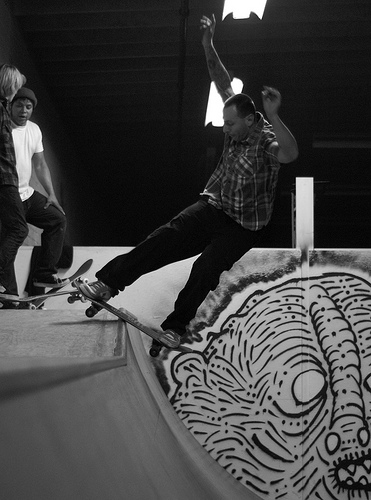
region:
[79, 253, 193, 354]
person on the skate board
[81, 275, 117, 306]
man wearing gray shoes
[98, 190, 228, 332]
man wearing black pants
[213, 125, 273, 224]
man wearing a plaid shirt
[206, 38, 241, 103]
man with tattoo on its arm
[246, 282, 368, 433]
graffiti on the wall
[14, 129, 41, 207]
man wearing a white shirt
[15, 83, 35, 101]
man wearing a hat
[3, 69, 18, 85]
man with blond hair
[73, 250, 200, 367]
man doing a trick on a skate board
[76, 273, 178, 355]
skateboard on the edge of the ramp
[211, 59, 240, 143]
light fixture in the ceiling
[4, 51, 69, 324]
people standing at the top of the ramp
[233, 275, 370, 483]
wall painted graffiti style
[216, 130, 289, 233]
person wearing a plaid shirt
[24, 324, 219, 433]
skate ramp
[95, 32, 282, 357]
skater riding a skateboard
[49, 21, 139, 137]
rafters in the ceiling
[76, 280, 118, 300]
boy wearing tennis shoes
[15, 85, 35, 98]
boy wearing a beanie hat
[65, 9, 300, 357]
Man on skateboard on the edge of slope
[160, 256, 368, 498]
Graffiti drawing on the slope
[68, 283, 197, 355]
Skateboard ridden by a man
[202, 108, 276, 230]
Checkered shirt worn by a man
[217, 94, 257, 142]
Man's head looking at skateboard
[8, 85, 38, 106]
Grey hat on the head of a man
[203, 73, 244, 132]
Lightings on the ceiling in the background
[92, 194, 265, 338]
Black pants worn by man on skateboard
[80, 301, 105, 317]
Black wheels of the skate board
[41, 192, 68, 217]
Man's hand placed on his thigh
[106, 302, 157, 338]
a skateboard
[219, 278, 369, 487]
a drawing on the wall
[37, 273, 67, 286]
a shoe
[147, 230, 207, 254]
man is wearing pants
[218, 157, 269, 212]
a plaid shirt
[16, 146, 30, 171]
a white shirt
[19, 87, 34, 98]
man is wearing a beanie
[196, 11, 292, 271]
a man on a skateboard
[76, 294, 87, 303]
wheel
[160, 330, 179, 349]
the mans shoe on the skateboard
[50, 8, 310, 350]
Guy skateboarding in rink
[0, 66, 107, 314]
two guys on skateboards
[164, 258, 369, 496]
animal design on cement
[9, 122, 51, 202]
white shirt on guy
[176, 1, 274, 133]
two florescent lights on ceiling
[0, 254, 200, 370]
three skateboards on cement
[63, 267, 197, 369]
skateboard on edge of cement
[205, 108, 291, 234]
striped short sleeve dress shirt on guy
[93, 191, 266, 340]
dark jeans on guy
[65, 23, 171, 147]
several lined ceiling boards